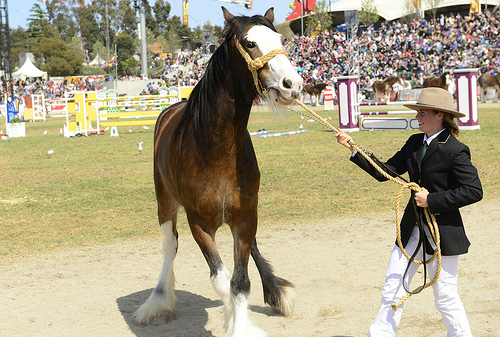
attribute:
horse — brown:
[158, 31, 338, 297]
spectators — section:
[294, 33, 484, 76]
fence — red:
[337, 78, 360, 132]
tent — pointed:
[13, 57, 52, 73]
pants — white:
[389, 259, 469, 337]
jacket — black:
[359, 132, 480, 248]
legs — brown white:
[146, 229, 288, 326]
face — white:
[222, 19, 307, 112]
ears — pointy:
[215, 11, 285, 40]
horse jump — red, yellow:
[85, 102, 153, 120]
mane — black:
[190, 59, 236, 122]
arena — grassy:
[6, 143, 161, 241]